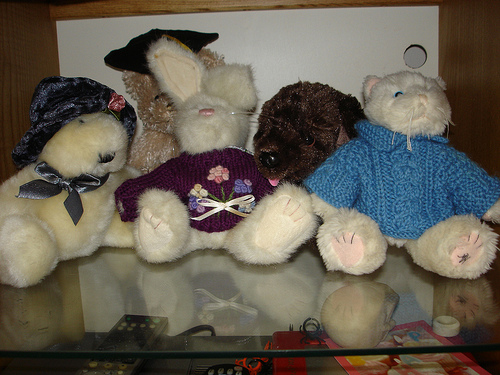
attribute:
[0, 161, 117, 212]
bow — Blue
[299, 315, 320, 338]
ring — plastic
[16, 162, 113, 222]
ribbon — grey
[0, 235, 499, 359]
shelf — Glass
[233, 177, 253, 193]
flower — purple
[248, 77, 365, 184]
dog — brown, plush, stuffed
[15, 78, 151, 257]
bear — white, plush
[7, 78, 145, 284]
animal — stuffed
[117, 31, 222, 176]
animal — stuffed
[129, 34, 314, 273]
animal — stuffed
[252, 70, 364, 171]
animal — stuffed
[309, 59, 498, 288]
animal — stuffed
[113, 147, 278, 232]
sweater — purple, knit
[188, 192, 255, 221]
bow — white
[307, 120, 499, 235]
sweater — blue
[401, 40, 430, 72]
hole — circle shaped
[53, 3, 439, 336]
board — white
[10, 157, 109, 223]
bow — silver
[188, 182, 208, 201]
flower — white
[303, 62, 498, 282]
toy — White, stuffed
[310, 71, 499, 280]
cat — plush, stuffed, white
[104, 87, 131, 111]
rose — pink